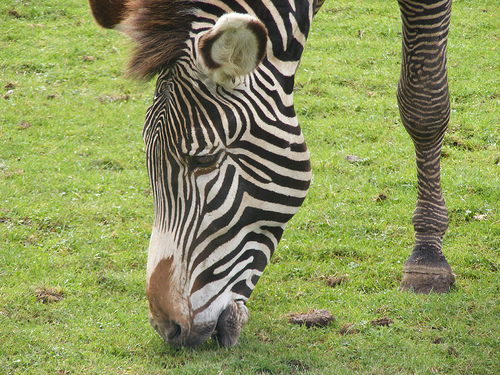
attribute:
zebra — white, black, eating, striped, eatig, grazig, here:
[85, 1, 461, 353]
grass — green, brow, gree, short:
[145, 343, 253, 372]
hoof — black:
[398, 247, 456, 296]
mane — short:
[121, 0, 197, 84]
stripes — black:
[198, 200, 269, 251]